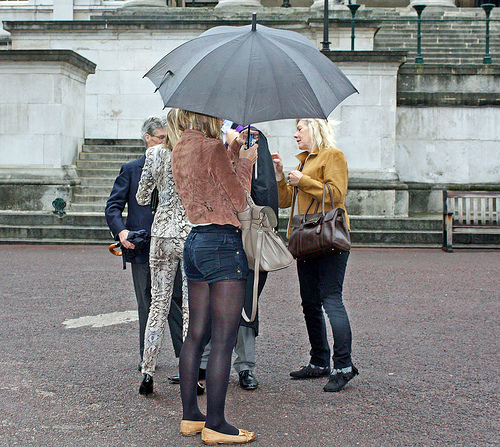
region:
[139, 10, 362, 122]
a large umbrella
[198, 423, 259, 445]
a woman's brown shoe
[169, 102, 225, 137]
part of a woman's blonde hair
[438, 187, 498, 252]
part of a wooden bench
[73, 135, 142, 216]
part of a outdoor stairway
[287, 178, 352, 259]
a woman's large purse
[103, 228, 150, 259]
part of an umbrella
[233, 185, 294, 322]
a woman's gray handbag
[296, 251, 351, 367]
a woman's blue jean pants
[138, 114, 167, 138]
part of a man's short cut gray hair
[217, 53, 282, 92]
Part of the umbrella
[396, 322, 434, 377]
Part of the ground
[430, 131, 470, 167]
Part of the building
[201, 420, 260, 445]
The right foot of the woman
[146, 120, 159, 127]
Part of the hair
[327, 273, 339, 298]
Part of the pants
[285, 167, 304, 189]
The left hand of the woman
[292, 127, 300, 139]
The nose of the woman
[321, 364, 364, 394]
The left foot of the woman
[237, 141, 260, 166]
The right hand of the woman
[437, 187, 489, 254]
Small wooden bench on pavement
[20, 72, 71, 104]
Small part of white brick wall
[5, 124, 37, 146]
Small part of white brick wall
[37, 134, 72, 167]
Small part of white brick wall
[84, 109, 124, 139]
Small part of white brick wall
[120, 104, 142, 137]
Small part of white brick wall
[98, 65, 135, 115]
Small part of white brick wall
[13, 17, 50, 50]
Small part of white brick wall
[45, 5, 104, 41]
Small part of white brick wall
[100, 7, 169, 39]
Small part of white brick wall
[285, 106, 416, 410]
This is a person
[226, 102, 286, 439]
This is a person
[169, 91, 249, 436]
This is a person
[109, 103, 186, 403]
This is a person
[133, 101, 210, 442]
This is a person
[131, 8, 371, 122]
The umbrella is black.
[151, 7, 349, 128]
The umbrella is open.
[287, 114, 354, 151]
The woman has light hair.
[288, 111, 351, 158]
The woman's hair is blonde.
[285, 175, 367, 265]
The woman is holding a purse.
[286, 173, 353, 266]
The purse is brown.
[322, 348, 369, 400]
The woman is wearing a black shoe.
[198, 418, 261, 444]
The woman is wearing a tan shoe.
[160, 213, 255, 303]
The woman is wearing blue shorts.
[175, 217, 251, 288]
The blue shorts are denim.